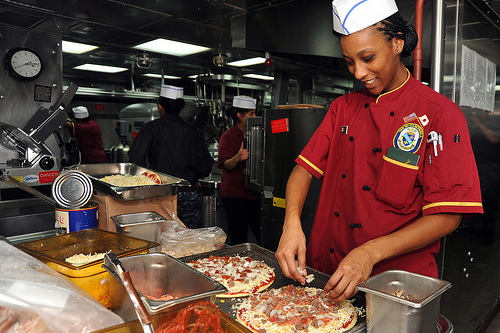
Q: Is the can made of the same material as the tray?
A: Yes, both the can and the tray are made of metal.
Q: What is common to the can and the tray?
A: The material, both the can and the tray are metallic.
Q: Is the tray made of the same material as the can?
A: Yes, both the tray and the can are made of metal.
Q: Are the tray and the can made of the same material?
A: Yes, both the tray and the can are made of metal.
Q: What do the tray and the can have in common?
A: The material, both the tray and the can are metallic.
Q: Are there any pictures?
A: No, there are no pictures.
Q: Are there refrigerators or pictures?
A: No, there are no pictures or refrigerators.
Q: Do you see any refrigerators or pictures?
A: No, there are no pictures or refrigerators.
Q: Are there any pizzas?
A: Yes, there is a pizza.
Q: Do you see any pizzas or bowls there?
A: Yes, there is a pizza.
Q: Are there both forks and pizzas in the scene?
A: No, there is a pizza but no forks.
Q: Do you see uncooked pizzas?
A: Yes, there is an uncooked pizza.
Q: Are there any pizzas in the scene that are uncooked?
A: Yes, there is a pizza that is uncooked.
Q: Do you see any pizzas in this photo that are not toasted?
A: Yes, there is a uncooked pizza.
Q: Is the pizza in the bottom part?
A: Yes, the pizza is in the bottom of the image.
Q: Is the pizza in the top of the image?
A: No, the pizza is in the bottom of the image.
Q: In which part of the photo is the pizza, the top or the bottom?
A: The pizza is in the bottom of the image.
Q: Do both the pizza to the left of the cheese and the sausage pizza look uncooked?
A: Yes, both the pizza and the pizza are uncooked.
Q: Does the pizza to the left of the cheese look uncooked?
A: Yes, the pizza is uncooked.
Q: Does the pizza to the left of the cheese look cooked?
A: No, the pizza is uncooked.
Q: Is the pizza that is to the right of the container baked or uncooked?
A: The pizza is uncooked.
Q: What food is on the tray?
A: The food is a pizza.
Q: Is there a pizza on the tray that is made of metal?
A: Yes, there is a pizza on the tray.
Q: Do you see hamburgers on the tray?
A: No, there is a pizza on the tray.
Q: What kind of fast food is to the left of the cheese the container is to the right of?
A: The food is a pizza.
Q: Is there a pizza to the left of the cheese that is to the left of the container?
A: Yes, there is a pizza to the left of the cheese.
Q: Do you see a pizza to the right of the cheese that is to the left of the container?
A: No, the pizza is to the left of the cheese.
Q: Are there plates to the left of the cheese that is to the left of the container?
A: No, there is a pizza to the left of the cheese.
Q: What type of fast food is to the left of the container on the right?
A: The food is a pizza.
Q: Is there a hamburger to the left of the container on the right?
A: No, there is a pizza to the left of the container.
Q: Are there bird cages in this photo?
A: No, there are no bird cages.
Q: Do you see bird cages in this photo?
A: No, there are no bird cages.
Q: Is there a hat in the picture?
A: Yes, there is a hat.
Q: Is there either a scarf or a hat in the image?
A: Yes, there is a hat.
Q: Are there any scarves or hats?
A: Yes, there is a hat.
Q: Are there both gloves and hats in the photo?
A: No, there is a hat but no gloves.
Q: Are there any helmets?
A: No, there are no helmets.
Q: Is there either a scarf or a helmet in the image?
A: No, there are no helmets or scarves.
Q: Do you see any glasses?
A: No, there are no glasses.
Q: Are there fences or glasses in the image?
A: No, there are no glasses or fences.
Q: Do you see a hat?
A: Yes, there is a hat.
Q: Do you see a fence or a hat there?
A: Yes, there is a hat.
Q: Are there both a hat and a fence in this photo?
A: No, there is a hat but no fences.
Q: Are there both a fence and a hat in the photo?
A: No, there is a hat but no fences.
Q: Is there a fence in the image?
A: No, there are no fences.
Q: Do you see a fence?
A: No, there are no fences.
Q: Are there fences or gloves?
A: No, there are no fences or gloves.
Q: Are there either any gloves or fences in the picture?
A: No, there are no fences or gloves.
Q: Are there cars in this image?
A: No, there are no cars.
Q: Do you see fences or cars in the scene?
A: No, there are no cars or fences.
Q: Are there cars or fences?
A: No, there are no cars or fences.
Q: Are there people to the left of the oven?
A: Yes, there is a person to the left of the oven.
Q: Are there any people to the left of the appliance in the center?
A: Yes, there is a person to the left of the oven.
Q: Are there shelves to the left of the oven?
A: No, there is a person to the left of the oven.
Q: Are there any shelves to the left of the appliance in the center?
A: No, there is a person to the left of the oven.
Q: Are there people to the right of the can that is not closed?
A: Yes, there is a person to the right of the can.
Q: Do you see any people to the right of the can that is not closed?
A: Yes, there is a person to the right of the can.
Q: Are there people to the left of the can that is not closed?
A: No, the person is to the right of the can.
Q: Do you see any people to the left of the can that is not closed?
A: No, the person is to the right of the can.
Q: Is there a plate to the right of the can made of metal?
A: No, there is a person to the right of the can.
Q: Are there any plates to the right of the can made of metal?
A: No, there is a person to the right of the can.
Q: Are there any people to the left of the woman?
A: Yes, there is a person to the left of the woman.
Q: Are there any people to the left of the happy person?
A: Yes, there is a person to the left of the woman.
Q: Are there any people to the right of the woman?
A: No, the person is to the left of the woman.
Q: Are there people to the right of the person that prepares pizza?
A: No, the person is to the left of the woman.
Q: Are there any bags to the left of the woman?
A: No, there is a person to the left of the woman.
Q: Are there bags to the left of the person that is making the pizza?
A: No, there is a person to the left of the woman.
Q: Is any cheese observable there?
A: Yes, there is cheese.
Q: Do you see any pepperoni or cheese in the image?
A: Yes, there is cheese.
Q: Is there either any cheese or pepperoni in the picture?
A: Yes, there is cheese.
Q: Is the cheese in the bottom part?
A: Yes, the cheese is in the bottom of the image.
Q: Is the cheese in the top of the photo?
A: No, the cheese is in the bottom of the image.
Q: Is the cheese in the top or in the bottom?
A: The cheese is in the bottom of the image.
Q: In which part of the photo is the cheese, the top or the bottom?
A: The cheese is in the bottom of the image.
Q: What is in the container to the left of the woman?
A: The cheese is in the container.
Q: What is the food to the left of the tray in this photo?
A: The food is cheese.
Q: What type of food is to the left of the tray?
A: The food is cheese.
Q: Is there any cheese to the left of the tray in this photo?
A: Yes, there is cheese to the left of the tray.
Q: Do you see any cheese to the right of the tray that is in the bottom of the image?
A: No, the cheese is to the left of the tray.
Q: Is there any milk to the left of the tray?
A: No, there is cheese to the left of the tray.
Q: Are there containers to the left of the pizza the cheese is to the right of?
A: Yes, there is a container to the left of the pizza.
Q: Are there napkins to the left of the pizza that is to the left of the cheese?
A: No, there is a container to the left of the pizza.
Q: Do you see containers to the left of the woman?
A: Yes, there is a container to the left of the woman.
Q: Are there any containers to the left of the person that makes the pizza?
A: Yes, there is a container to the left of the woman.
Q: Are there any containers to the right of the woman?
A: No, the container is to the left of the woman.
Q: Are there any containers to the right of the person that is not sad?
A: No, the container is to the left of the woman.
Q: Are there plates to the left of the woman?
A: No, there is a container to the left of the woman.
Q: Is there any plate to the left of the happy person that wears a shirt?
A: No, there is a container to the left of the woman.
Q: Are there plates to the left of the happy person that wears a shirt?
A: No, there is a container to the left of the woman.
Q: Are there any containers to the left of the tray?
A: Yes, there is a container to the left of the tray.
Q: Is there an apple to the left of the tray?
A: No, there is a container to the left of the tray.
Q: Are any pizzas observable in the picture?
A: Yes, there is a pizza.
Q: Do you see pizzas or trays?
A: Yes, there is a pizza.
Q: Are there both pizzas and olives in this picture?
A: No, there is a pizza but no olives.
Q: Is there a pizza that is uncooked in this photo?
A: Yes, there is an uncooked pizza.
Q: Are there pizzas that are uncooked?
A: Yes, there is a pizza that is uncooked.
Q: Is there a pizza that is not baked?
A: Yes, there is a uncooked pizza.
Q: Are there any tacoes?
A: No, there are no tacoes.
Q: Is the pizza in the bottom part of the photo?
A: Yes, the pizza is in the bottom of the image.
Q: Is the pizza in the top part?
A: No, the pizza is in the bottom of the image.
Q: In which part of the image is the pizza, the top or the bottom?
A: The pizza is in the bottom of the image.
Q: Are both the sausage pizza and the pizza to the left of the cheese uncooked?
A: Yes, both the pizza and the pizza are uncooked.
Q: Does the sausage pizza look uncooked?
A: Yes, the pizza is uncooked.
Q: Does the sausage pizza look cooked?
A: No, the pizza is uncooked.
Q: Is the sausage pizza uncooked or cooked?
A: The pizza is uncooked.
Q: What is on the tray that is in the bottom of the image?
A: The pizza is on the tray.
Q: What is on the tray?
A: The pizza is on the tray.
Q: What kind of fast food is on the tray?
A: The food is a pizza.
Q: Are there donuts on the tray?
A: No, there is a pizza on the tray.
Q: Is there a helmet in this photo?
A: No, there are no helmets.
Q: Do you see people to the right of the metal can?
A: Yes, there is a person to the right of the can.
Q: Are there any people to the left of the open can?
A: No, the person is to the right of the can.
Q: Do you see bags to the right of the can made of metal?
A: No, there is a person to the right of the can.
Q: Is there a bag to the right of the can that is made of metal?
A: No, there is a person to the right of the can.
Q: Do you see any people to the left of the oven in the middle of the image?
A: Yes, there is a person to the left of the oven.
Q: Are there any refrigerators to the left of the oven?
A: No, there is a person to the left of the oven.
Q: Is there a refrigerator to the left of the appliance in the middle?
A: No, there is a person to the left of the oven.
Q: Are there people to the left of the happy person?
A: Yes, there is a person to the left of the woman.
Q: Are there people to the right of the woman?
A: No, the person is to the left of the woman.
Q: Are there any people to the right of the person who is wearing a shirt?
A: No, the person is to the left of the woman.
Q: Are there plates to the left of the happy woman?
A: No, there is a person to the left of the woman.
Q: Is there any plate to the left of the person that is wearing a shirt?
A: No, there is a person to the left of the woman.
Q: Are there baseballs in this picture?
A: No, there are no baseballs.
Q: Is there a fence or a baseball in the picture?
A: No, there are no baseballs or fences.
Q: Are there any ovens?
A: Yes, there is an oven.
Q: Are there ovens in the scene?
A: Yes, there is an oven.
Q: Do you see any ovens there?
A: Yes, there is an oven.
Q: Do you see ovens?
A: Yes, there is an oven.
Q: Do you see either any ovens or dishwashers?
A: Yes, there is an oven.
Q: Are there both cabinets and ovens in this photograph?
A: No, there is an oven but no cabinets.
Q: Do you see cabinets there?
A: No, there are no cabinets.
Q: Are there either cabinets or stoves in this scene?
A: No, there are no cabinets or stoves.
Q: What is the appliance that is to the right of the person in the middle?
A: The appliance is an oven.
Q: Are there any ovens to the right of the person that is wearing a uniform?
A: Yes, there is an oven to the right of the person.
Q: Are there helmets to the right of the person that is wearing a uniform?
A: No, there is an oven to the right of the person.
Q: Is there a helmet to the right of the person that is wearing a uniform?
A: No, there is an oven to the right of the person.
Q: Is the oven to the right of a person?
A: Yes, the oven is to the right of a person.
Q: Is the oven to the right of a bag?
A: No, the oven is to the right of a person.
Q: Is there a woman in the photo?
A: Yes, there is a woman.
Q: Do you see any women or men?
A: Yes, there is a woman.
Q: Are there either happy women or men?
A: Yes, there is a happy woman.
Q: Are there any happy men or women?
A: Yes, there is a happy woman.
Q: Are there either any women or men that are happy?
A: Yes, the woman is happy.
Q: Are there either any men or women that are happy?
A: Yes, the woman is happy.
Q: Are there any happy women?
A: Yes, there is a happy woman.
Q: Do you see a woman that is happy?
A: Yes, there is a woman that is happy.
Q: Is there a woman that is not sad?
A: Yes, there is a happy woman.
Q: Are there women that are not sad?
A: Yes, there is a happy woman.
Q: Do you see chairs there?
A: No, there are no chairs.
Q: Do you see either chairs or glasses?
A: No, there are no chairs or glasses.